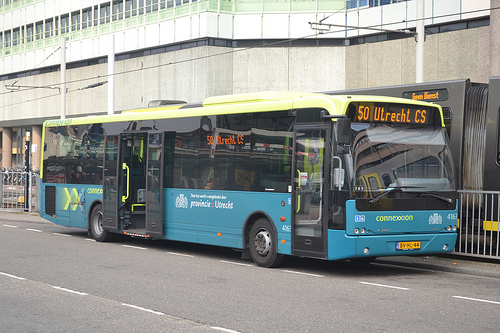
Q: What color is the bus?
A: Blue and yellow.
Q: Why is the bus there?
A: Transporting people.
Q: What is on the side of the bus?
A: Letters.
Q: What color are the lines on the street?
A: White.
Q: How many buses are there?
A: One.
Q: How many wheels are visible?
A: Two.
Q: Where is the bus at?
A: City street.